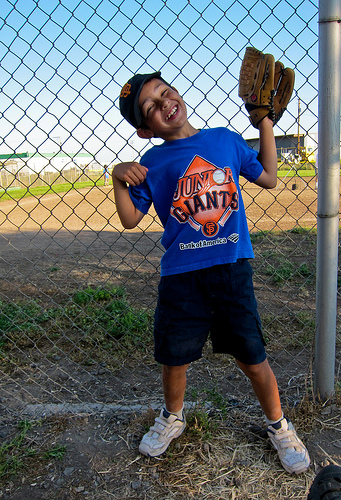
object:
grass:
[5, 415, 83, 494]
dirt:
[13, 414, 137, 486]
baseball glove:
[238, 47, 296, 129]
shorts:
[153, 257, 267, 364]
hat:
[119, 71, 162, 131]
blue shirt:
[129, 128, 264, 276]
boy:
[111, 47, 311, 477]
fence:
[0, 0, 340, 415]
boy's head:
[118, 71, 188, 139]